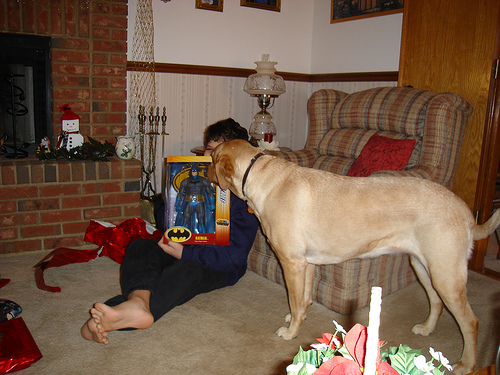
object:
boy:
[75, 116, 260, 346]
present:
[158, 149, 233, 250]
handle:
[363, 283, 385, 375]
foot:
[88, 300, 156, 332]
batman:
[161, 152, 235, 248]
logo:
[163, 224, 195, 244]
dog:
[202, 136, 500, 374]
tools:
[134, 97, 173, 207]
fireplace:
[2, 0, 144, 260]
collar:
[240, 149, 269, 200]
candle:
[257, 131, 282, 152]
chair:
[247, 82, 475, 317]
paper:
[31, 212, 149, 297]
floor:
[0, 250, 500, 374]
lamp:
[243, 50, 286, 154]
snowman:
[53, 101, 88, 158]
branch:
[40, 136, 116, 162]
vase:
[114, 130, 138, 160]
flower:
[290, 320, 395, 374]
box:
[162, 152, 232, 248]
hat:
[58, 103, 83, 122]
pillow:
[344, 129, 415, 180]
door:
[399, 0, 499, 272]